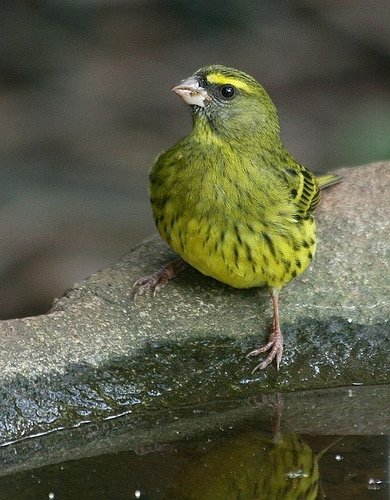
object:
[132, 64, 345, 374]
bird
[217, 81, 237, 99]
eye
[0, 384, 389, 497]
water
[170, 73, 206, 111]
beak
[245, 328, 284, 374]
foot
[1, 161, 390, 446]
stone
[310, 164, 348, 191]
tail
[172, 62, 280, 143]
head